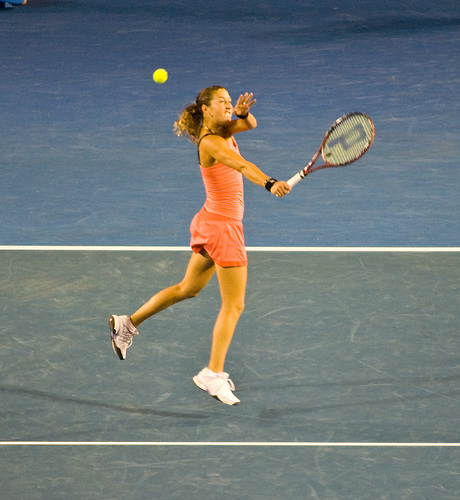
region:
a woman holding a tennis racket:
[160, 80, 407, 208]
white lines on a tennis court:
[37, 431, 395, 456]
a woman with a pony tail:
[171, 67, 259, 145]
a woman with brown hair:
[168, 69, 248, 149]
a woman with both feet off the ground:
[106, 63, 256, 394]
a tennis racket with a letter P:
[299, 99, 392, 189]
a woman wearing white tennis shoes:
[99, 76, 260, 394]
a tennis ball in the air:
[143, 53, 174, 110]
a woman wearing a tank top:
[188, 90, 253, 232]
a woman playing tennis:
[117, 44, 393, 370]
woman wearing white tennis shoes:
[202, 361, 242, 419]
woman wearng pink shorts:
[165, 193, 261, 285]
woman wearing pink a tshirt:
[185, 132, 257, 218]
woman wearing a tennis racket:
[258, 93, 381, 219]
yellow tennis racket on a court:
[149, 34, 172, 101]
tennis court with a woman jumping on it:
[31, 30, 144, 244]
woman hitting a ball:
[186, 82, 256, 392]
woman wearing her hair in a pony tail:
[167, 49, 261, 248]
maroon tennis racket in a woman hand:
[263, 94, 373, 214]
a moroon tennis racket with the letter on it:
[280, 92, 381, 197]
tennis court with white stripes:
[12, 159, 102, 485]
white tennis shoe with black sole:
[99, 293, 145, 372]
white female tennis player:
[90, 44, 415, 435]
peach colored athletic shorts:
[166, 195, 285, 292]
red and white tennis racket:
[271, 103, 386, 211]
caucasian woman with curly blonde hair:
[154, 74, 249, 131]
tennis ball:
[136, 54, 184, 89]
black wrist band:
[257, 168, 280, 198]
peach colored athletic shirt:
[194, 123, 247, 227]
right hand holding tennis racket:
[257, 157, 320, 231]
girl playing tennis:
[132, 26, 319, 411]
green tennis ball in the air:
[122, 36, 216, 137]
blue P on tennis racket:
[270, 92, 413, 211]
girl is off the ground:
[99, 46, 289, 454]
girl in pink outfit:
[181, 105, 265, 287]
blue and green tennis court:
[21, 35, 421, 481]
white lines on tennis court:
[13, 226, 295, 490]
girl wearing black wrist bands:
[211, 76, 337, 248]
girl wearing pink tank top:
[168, 101, 267, 224]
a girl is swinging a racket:
[113, 53, 441, 354]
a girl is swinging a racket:
[62, 18, 348, 296]